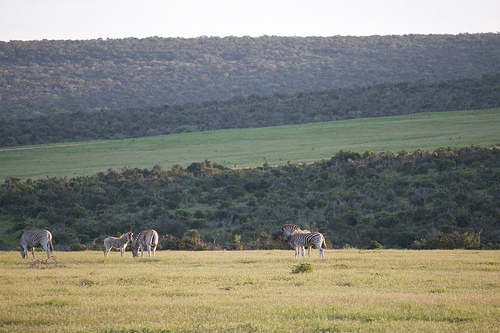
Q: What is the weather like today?
A: It is clear.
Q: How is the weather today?
A: It is clear.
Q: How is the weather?
A: It is clear.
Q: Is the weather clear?
A: Yes, it is clear.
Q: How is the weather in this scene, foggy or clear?
A: It is clear.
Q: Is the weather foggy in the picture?
A: No, it is clear.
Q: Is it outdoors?
A: Yes, it is outdoors.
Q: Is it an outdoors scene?
A: Yes, it is outdoors.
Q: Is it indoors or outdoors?
A: It is outdoors.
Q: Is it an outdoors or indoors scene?
A: It is outdoors.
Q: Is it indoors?
A: No, it is outdoors.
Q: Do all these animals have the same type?
A: Yes, all the animals are zebras.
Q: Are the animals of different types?
A: No, all the animals are zebras.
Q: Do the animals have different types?
A: No, all the animals are zebras.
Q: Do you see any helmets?
A: No, there are no helmets.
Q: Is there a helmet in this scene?
A: No, there are no helmets.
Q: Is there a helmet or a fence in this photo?
A: No, there are no helmets or fences.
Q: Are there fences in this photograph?
A: No, there are no fences.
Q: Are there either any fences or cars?
A: No, there are no fences or cars.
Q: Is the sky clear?
A: Yes, the sky is clear.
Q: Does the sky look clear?
A: Yes, the sky is clear.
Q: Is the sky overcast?
A: No, the sky is clear.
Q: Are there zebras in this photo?
A: Yes, there is a zebra.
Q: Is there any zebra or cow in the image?
A: Yes, there is a zebra.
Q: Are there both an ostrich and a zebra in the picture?
A: No, there is a zebra but no ostriches.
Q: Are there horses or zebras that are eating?
A: Yes, the zebra is eating.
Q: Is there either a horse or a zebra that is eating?
A: Yes, the zebra is eating.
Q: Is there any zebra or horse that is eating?
A: Yes, the zebra is eating.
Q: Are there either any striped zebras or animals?
A: Yes, there is a striped zebra.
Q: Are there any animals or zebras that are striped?
A: Yes, the zebra is striped.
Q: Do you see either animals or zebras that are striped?
A: Yes, the zebra is striped.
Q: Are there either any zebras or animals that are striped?
A: Yes, the zebra is striped.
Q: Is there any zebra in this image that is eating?
A: Yes, there is a zebra that is eating.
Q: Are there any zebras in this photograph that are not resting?
A: Yes, there is a zebra that is eating.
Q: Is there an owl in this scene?
A: No, there are no owls.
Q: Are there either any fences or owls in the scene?
A: No, there are no owls or fences.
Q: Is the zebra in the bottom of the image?
A: Yes, the zebra is in the bottom of the image.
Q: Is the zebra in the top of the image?
A: No, the zebra is in the bottom of the image.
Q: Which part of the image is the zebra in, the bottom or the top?
A: The zebra is in the bottom of the image.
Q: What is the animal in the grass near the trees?
A: The animal is a zebra.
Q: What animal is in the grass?
A: The animal is a zebra.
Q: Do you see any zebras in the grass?
A: Yes, there is a zebra in the grass.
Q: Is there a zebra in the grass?
A: Yes, there is a zebra in the grass.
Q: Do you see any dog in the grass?
A: No, there is a zebra in the grass.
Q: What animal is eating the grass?
A: The zebra is eating the grass.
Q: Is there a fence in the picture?
A: No, there are no fences.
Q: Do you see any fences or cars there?
A: No, there are no fences or cars.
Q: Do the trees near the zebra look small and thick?
A: Yes, the trees are small and thick.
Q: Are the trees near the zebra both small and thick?
A: Yes, the trees are small and thick.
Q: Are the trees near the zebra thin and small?
A: No, the trees are small but thick.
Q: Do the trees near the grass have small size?
A: Yes, the trees are small.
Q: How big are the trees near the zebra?
A: The trees are small.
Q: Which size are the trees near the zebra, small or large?
A: The trees are small.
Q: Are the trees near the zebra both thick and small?
A: Yes, the trees are thick and small.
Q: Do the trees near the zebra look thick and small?
A: Yes, the trees are thick and small.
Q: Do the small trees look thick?
A: Yes, the trees are thick.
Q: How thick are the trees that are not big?
A: The trees are thick.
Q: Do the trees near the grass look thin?
A: No, the trees are thick.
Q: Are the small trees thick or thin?
A: The trees are thick.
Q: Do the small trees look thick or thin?
A: The trees are thick.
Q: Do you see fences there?
A: No, there are no fences.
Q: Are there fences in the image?
A: No, there are no fences.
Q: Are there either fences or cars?
A: No, there are no fences or cars.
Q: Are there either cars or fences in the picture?
A: No, there are no fences or cars.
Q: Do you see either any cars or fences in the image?
A: No, there are no fences or cars.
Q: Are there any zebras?
A: Yes, there is a zebra.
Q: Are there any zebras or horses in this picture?
A: Yes, there is a zebra.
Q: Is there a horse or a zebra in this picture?
A: Yes, there is a zebra.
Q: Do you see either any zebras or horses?
A: Yes, there is a zebra.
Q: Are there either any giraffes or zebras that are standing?
A: Yes, the zebra is standing.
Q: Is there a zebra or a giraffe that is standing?
A: Yes, the zebra is standing.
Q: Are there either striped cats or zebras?
A: Yes, there is a striped zebra.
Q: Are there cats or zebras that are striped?
A: Yes, the zebra is striped.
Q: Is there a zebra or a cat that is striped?
A: Yes, the zebra is striped.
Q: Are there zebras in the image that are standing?
A: Yes, there is a zebra that is standing.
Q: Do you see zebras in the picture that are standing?
A: Yes, there is a zebra that is standing.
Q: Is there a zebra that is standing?
A: Yes, there is a zebra that is standing.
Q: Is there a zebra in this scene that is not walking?
A: Yes, there is a zebra that is standing.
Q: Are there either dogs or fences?
A: No, there are no fences or dogs.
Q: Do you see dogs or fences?
A: No, there are no fences or dogs.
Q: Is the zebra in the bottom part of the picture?
A: Yes, the zebra is in the bottom of the image.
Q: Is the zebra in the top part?
A: No, the zebra is in the bottom of the image.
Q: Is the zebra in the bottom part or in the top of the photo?
A: The zebra is in the bottom of the image.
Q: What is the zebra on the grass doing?
A: The zebra is standing.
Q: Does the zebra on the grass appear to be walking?
A: No, the zebra is standing.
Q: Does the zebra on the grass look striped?
A: Yes, the zebra is striped.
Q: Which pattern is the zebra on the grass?
A: The zebra is striped.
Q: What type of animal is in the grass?
A: The animal is a zebra.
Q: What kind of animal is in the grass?
A: The animal is a zebra.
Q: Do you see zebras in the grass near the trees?
A: Yes, there is a zebra in the grass.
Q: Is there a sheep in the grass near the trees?
A: No, there is a zebra in the grass.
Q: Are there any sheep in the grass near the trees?
A: No, there is a zebra in the grass.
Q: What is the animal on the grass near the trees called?
A: The animal is a zebra.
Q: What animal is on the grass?
A: The animal is a zebra.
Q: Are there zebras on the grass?
A: Yes, there is a zebra on the grass.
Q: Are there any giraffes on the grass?
A: No, there is a zebra on the grass.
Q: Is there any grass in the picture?
A: Yes, there is grass.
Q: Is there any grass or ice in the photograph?
A: Yes, there is grass.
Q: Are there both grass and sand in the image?
A: No, there is grass but no sand.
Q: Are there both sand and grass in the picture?
A: No, there is grass but no sand.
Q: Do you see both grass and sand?
A: No, there is grass but no sand.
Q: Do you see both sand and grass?
A: No, there is grass but no sand.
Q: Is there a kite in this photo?
A: No, there are no kites.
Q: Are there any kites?
A: No, there are no kites.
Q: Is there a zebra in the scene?
A: Yes, there is a zebra.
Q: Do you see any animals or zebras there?
A: Yes, there is a zebra.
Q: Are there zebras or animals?
A: Yes, there is a zebra.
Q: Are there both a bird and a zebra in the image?
A: No, there is a zebra but no birds.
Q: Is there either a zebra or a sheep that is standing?
A: Yes, the zebra is standing.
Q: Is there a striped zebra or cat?
A: Yes, there is a striped zebra.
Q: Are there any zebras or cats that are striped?
A: Yes, the zebra is striped.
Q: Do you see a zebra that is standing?
A: Yes, there is a zebra that is standing.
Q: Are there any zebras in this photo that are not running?
A: Yes, there is a zebra that is standing.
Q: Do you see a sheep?
A: No, there is no sheep.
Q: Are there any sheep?
A: No, there are no sheep.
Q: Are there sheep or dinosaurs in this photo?
A: No, there are no sheep or dinosaurs.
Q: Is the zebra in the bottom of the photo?
A: Yes, the zebra is in the bottom of the image.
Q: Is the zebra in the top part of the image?
A: No, the zebra is in the bottom of the image.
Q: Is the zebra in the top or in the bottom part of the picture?
A: The zebra is in the bottom of the image.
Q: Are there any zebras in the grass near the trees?
A: Yes, there is a zebra in the grass.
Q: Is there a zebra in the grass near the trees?
A: Yes, there is a zebra in the grass.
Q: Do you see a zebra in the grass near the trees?
A: Yes, there is a zebra in the grass.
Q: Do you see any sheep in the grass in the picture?
A: No, there is a zebra in the grass.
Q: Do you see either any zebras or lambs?
A: Yes, there is a zebra.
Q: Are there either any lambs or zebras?
A: Yes, there is a zebra.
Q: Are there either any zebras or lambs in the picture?
A: Yes, there is a zebra.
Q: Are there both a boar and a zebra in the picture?
A: No, there is a zebra but no boars.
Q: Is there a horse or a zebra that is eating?
A: Yes, the zebra is eating.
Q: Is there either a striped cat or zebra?
A: Yes, there is a striped zebra.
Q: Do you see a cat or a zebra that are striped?
A: Yes, the zebra is striped.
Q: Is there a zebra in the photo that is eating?
A: Yes, there is a zebra that is eating.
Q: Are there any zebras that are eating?
A: Yes, there is a zebra that is eating.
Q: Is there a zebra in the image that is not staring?
A: Yes, there is a zebra that is eating.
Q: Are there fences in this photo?
A: No, there are no fences.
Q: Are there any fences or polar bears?
A: No, there are no fences or polar bears.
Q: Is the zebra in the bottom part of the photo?
A: Yes, the zebra is in the bottom of the image.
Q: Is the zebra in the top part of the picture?
A: No, the zebra is in the bottom of the image.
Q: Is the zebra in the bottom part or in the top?
A: The zebra is in the bottom of the image.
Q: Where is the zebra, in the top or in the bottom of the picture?
A: The zebra is in the bottom of the image.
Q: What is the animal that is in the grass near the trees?
A: The animal is a zebra.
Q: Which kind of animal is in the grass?
A: The animal is a zebra.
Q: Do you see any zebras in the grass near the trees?
A: Yes, there is a zebra in the grass.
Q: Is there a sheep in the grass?
A: No, there is a zebra in the grass.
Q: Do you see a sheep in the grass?
A: No, there is a zebra in the grass.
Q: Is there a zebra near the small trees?
A: Yes, there is a zebra near the trees.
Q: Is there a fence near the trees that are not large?
A: No, there is a zebra near the trees.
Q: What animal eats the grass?
A: The zebra eats the grass.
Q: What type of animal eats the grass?
A: The animal is a zebra.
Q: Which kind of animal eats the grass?
A: The animal is a zebra.